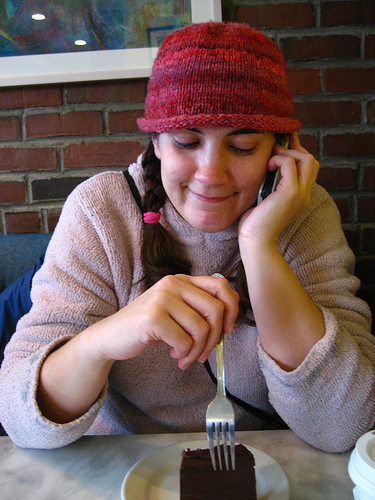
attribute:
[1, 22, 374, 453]
woman — smiling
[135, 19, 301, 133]
hat — red, knit, wool, knitted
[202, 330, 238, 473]
fork — silver, metal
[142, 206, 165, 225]
elastic — pink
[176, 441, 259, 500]
cake — chocolate, brown, big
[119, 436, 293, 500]
plate — white, small, round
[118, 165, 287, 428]
strap — black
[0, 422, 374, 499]
table — marble, gray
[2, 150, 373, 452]
sweater — pink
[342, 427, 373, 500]
plates — stacked, white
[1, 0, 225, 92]
picture — colorful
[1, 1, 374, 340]
wall — brick, red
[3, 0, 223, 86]
frame — white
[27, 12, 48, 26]
light — reflected, round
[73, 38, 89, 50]
light — reflected, round